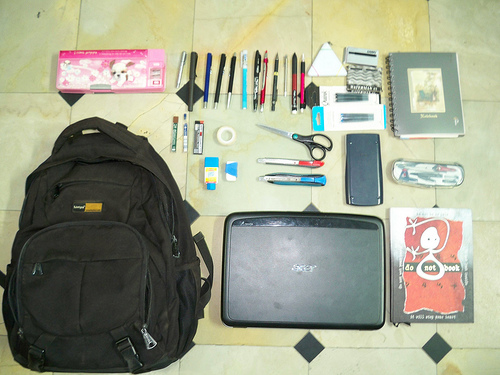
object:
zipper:
[142, 273, 157, 350]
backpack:
[2, 115, 216, 375]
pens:
[176, 50, 187, 89]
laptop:
[220, 210, 385, 330]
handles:
[296, 132, 334, 160]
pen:
[240, 49, 248, 110]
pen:
[188, 51, 198, 112]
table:
[1, 4, 478, 369]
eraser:
[202, 154, 237, 189]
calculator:
[342, 131, 384, 208]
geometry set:
[55, 43, 165, 97]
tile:
[1, 1, 78, 95]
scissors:
[254, 122, 330, 162]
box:
[56, 47, 165, 93]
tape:
[214, 126, 234, 145]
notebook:
[388, 49, 465, 141]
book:
[387, 205, 474, 325]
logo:
[72, 202, 102, 213]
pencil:
[271, 52, 280, 110]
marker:
[291, 50, 299, 114]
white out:
[260, 173, 328, 187]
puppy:
[108, 58, 137, 88]